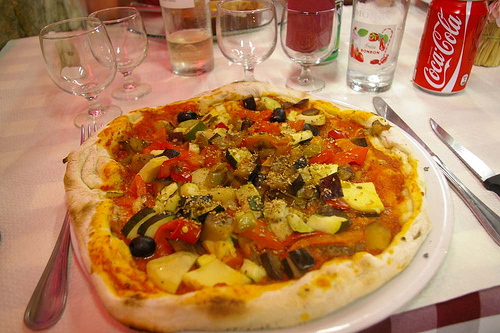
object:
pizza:
[63, 79, 430, 333]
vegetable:
[137, 155, 169, 183]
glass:
[38, 17, 125, 131]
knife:
[428, 119, 500, 198]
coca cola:
[411, 0, 489, 96]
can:
[408, 0, 489, 96]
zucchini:
[122, 211, 179, 241]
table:
[0, 1, 499, 332]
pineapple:
[339, 180, 384, 213]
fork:
[20, 123, 107, 332]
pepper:
[122, 174, 147, 204]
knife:
[370, 95, 499, 254]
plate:
[65, 93, 454, 332]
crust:
[102, 254, 395, 332]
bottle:
[344, 0, 410, 93]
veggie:
[118, 207, 155, 239]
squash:
[182, 259, 250, 289]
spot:
[421, 251, 430, 259]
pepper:
[168, 219, 203, 246]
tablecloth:
[360, 284, 499, 332]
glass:
[158, 1, 216, 77]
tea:
[166, 28, 214, 69]